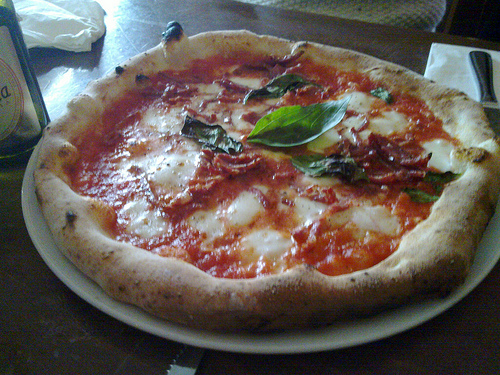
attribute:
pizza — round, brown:
[24, 32, 488, 349]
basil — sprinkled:
[176, 68, 369, 180]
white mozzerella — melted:
[132, 136, 199, 191]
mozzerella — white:
[227, 186, 293, 243]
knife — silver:
[469, 48, 499, 137]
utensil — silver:
[469, 48, 499, 152]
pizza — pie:
[50, 51, 465, 358]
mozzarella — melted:
[114, 62, 419, 262]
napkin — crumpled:
[17, 1, 125, 61]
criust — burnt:
[373, 54, 464, 113]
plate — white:
[24, 27, 494, 366]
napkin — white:
[400, 34, 485, 102]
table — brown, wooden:
[0, 0, 500, 373]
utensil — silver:
[470, 47, 499, 139]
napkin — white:
[420, 46, 499, 85]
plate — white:
[20, 136, 498, 354]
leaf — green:
[247, 99, 354, 153]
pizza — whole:
[31, 23, 498, 332]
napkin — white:
[421, 42, 498, 112]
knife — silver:
[468, 55, 494, 117]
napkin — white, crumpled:
[11, 2, 106, 52]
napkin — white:
[414, 38, 484, 105]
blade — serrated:
[163, 344, 184, 374]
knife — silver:
[158, 351, 212, 371]